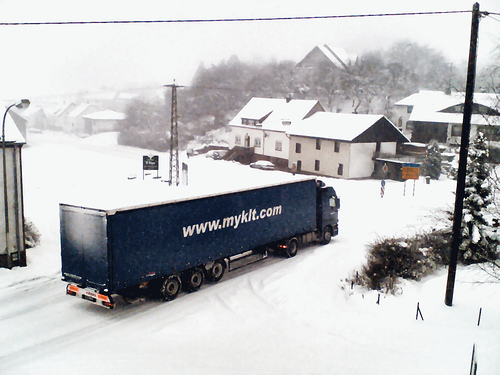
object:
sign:
[143, 156, 158, 171]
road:
[0, 181, 454, 375]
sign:
[403, 167, 419, 179]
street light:
[2, 97, 29, 263]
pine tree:
[461, 137, 500, 263]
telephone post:
[164, 85, 185, 186]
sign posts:
[416, 302, 419, 320]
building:
[289, 112, 410, 179]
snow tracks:
[0, 244, 322, 374]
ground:
[0, 135, 498, 375]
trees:
[190, 68, 224, 134]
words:
[223, 209, 256, 229]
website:
[182, 206, 281, 237]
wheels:
[149, 274, 182, 301]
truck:
[60, 178, 338, 310]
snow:
[0, 140, 499, 375]